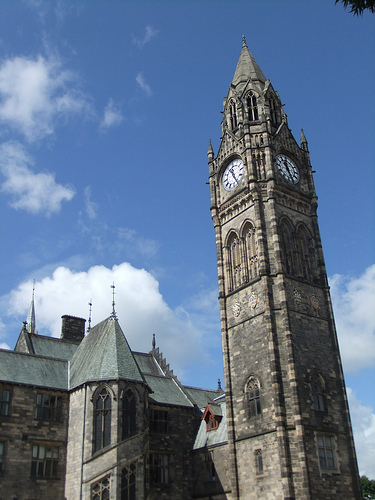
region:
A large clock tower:
[172, 19, 361, 497]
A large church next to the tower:
[5, 296, 222, 498]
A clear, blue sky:
[2, 2, 373, 456]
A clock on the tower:
[218, 151, 252, 193]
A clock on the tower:
[270, 148, 301, 184]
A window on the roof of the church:
[198, 398, 224, 435]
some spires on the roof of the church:
[21, 262, 137, 318]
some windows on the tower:
[238, 364, 336, 487]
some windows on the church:
[19, 387, 192, 493]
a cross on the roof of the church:
[18, 316, 31, 327]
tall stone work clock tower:
[204, 32, 362, 498]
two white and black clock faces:
[210, 143, 317, 204]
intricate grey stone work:
[205, 30, 311, 168]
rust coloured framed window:
[196, 398, 228, 434]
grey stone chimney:
[55, 308, 90, 346]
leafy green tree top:
[353, 469, 373, 499]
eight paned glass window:
[24, 387, 71, 429]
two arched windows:
[85, 381, 141, 459]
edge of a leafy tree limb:
[331, 0, 373, 20]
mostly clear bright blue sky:
[1, 31, 372, 498]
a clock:
[129, 81, 276, 252]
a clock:
[166, 34, 327, 274]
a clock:
[201, 118, 292, 256]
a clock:
[192, 49, 265, 239]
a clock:
[203, 172, 281, 242]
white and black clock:
[216, 152, 249, 188]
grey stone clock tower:
[210, 41, 355, 499]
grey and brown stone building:
[2, 275, 232, 498]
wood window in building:
[92, 388, 112, 454]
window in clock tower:
[228, 225, 263, 293]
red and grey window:
[199, 401, 222, 433]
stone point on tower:
[204, 136, 215, 151]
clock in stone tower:
[275, 153, 303, 188]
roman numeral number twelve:
[282, 154, 286, 160]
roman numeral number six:
[233, 181, 236, 185]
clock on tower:
[219, 154, 244, 192]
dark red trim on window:
[199, 401, 220, 431]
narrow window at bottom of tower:
[250, 446, 263, 477]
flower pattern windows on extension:
[82, 448, 160, 498]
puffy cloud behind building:
[10, 253, 196, 368]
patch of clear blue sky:
[124, 139, 211, 223]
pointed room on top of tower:
[215, 28, 284, 129]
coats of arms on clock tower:
[232, 293, 259, 317]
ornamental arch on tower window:
[241, 375, 260, 394]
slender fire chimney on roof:
[61, 313, 84, 337]